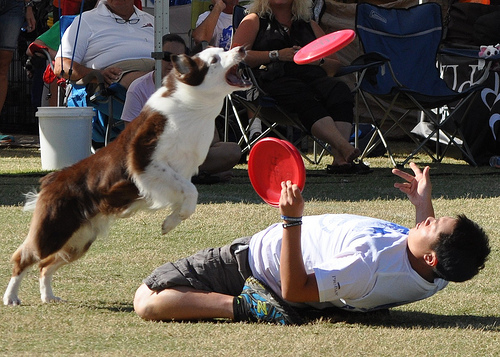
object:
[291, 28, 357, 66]
frisbee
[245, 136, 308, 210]
frisbees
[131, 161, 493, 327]
man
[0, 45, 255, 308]
dog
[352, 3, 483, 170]
chair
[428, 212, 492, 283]
hair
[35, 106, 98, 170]
bucket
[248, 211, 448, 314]
shirt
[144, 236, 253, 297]
shorts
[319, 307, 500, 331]
shadow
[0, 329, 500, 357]
ground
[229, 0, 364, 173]
woman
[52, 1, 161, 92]
man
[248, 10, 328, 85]
shirt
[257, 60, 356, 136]
pants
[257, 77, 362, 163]
legs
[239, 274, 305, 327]
shoe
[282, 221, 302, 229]
bracelet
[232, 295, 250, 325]
sock